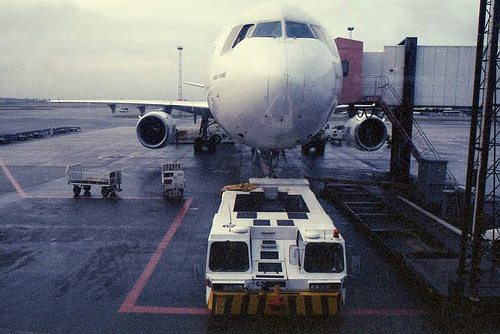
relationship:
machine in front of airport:
[200, 174, 352, 319] [45, 2, 391, 176]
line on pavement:
[2, 158, 454, 318] [13, 103, 496, 332]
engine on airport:
[135, 110, 180, 149] [45, 2, 391, 176]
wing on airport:
[48, 100, 209, 112] [45, 2, 391, 176]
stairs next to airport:
[375, 74, 460, 184] [45, 2, 391, 176]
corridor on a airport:
[329, 34, 490, 114] [45, 2, 391, 176]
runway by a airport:
[2, 103, 176, 324] [45, 2, 391, 176]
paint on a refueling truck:
[204, 287, 342, 317] [205, 166, 349, 324]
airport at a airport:
[45, 2, 391, 176] [8, 23, 498, 332]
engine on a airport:
[131, 110, 180, 146] [45, 2, 391, 176]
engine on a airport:
[342, 107, 387, 152] [45, 2, 391, 176]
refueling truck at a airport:
[205, 166, 349, 324] [8, 23, 498, 332]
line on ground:
[2, 158, 454, 318] [13, 105, 491, 328]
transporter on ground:
[64, 163, 124, 197] [13, 105, 491, 328]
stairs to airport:
[375, 74, 460, 184] [45, 2, 391, 176]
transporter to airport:
[328, 34, 497, 114] [45, 2, 391, 176]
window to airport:
[253, 18, 282, 38] [45, 2, 391, 176]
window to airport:
[231, 23, 251, 48] [45, 2, 391, 176]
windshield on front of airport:
[253, 18, 312, 39] [45, 2, 391, 176]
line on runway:
[2, 158, 454, 318] [2, 113, 452, 333]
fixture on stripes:
[267, 285, 288, 311] [206, 284, 343, 319]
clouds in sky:
[2, 0, 495, 100] [2, 3, 498, 98]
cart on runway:
[64, 159, 127, 199] [2, 113, 452, 333]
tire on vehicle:
[109, 191, 122, 204] [61, 156, 125, 203]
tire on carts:
[161, 186, 168, 196] [161, 162, 187, 201]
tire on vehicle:
[175, 191, 185, 201] [158, 158, 188, 202]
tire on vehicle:
[161, 181, 168, 197] [161, 162, 186, 200]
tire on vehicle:
[194, 138, 206, 152] [186, 130, 224, 160]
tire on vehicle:
[206, 134, 216, 154] [190, 132, 224, 165]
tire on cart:
[71, 185, 83, 194] [64, 163, 123, 196]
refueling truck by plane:
[205, 166, 327, 325] [68, 24, 399, 199]